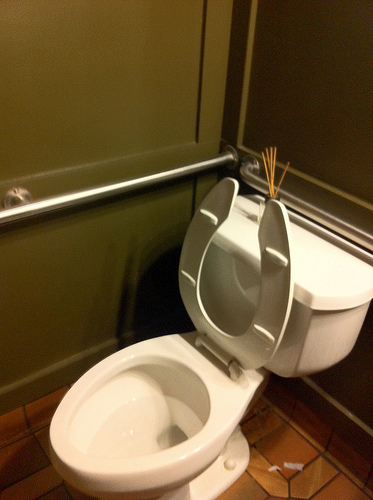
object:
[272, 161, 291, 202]
wooden sticks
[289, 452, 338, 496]
tile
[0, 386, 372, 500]
floor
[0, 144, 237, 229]
railing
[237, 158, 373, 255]
railing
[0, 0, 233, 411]
wall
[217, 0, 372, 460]
wall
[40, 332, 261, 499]
toilet bowl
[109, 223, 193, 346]
shade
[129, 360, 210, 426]
shade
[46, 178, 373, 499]
toilet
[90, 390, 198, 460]
water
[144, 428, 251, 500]
bottom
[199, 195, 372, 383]
tank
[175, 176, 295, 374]
seat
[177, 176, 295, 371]
lid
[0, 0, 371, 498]
bathroom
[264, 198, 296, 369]
edge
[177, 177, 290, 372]
underside